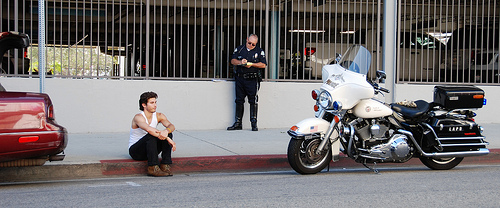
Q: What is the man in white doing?
A: Sitting.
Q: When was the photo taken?
A: Day time.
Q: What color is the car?
A: Red.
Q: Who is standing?
A: The cop.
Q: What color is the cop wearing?
A: Black.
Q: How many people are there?
A: Two.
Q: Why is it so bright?
A: Sun light.